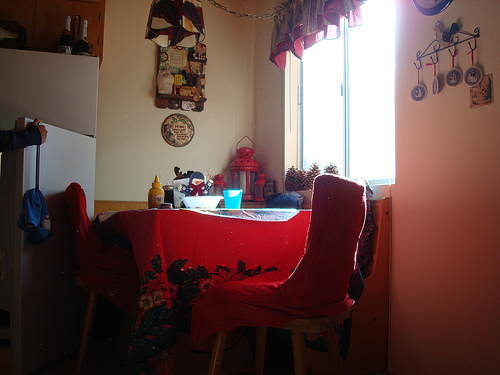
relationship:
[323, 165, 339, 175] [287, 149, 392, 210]
cone of windowsill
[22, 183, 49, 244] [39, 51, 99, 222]
blue towel on refrigerator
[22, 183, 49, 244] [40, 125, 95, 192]
blue towel on refrigerator door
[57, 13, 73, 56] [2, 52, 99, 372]
bottle on refrigerator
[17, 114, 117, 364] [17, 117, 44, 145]
fridge door held open by person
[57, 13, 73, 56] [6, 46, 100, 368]
bottle on top of refrigerator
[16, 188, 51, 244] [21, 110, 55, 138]
blue towel hanging on handle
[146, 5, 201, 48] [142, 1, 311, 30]
lamp hanging from ceiling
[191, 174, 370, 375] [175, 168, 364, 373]
chair on a kitchen chair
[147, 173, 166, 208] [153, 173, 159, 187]
bottle with a pointed top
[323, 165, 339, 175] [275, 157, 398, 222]
cone on windowsill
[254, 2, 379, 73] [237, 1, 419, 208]
curtain on window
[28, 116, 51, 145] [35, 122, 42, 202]
hand gripping a handle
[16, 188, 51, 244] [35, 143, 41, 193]
blue towel hanging on handle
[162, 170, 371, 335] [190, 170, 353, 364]
slip on chair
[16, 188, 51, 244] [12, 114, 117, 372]
blue towel hanging on fridge door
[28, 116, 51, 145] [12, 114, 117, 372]
hand opening fridge door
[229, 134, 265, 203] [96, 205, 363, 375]
lantern in corner of table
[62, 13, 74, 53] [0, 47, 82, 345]
bottle on top of fridge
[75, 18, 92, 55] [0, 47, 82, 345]
bottle on top of fridge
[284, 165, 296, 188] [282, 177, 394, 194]
cone in windowsill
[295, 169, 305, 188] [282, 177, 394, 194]
cone in windowsill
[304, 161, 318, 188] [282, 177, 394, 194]
cone in windowsill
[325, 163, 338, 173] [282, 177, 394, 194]
cone in windowsill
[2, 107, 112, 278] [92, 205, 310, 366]
refrigerator next to table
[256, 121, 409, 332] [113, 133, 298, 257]
chair at table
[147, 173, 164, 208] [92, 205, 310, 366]
bottle on table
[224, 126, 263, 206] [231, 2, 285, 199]
lantern in corner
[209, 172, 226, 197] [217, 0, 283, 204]
lantern in corner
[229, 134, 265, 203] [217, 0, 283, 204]
lantern in corner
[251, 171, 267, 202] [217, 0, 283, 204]
lantern in corner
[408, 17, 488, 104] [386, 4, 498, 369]
objects hanging on wall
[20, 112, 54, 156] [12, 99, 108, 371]
hand on door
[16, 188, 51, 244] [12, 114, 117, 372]
blue towel hanging from fridge door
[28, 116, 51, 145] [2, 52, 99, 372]
hand opens refrigerator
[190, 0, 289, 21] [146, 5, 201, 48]
chain running to lamp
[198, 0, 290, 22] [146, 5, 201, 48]
chain running to lamp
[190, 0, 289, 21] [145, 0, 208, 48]
chain running to light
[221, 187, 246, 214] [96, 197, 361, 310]
cup on table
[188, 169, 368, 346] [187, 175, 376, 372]
slip on a chair